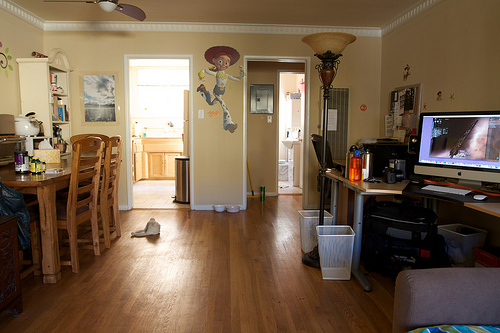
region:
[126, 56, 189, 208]
Daylight is shining from kitchen window.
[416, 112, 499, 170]
A TV is on.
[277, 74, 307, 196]
A light is on in the bathroom.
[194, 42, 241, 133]
A cartoon character is running.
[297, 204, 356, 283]
Two white baskets are on the floor.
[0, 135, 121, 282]
The chairs and table are wood.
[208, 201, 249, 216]
Two bowls are on the floor.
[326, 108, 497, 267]
The computer work station is on a table.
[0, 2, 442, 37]
Crown molding is on the wall.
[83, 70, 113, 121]
The picture is black,white and blue.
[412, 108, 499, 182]
computer monitor on large wooden desk top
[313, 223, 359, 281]
metal screen trash can next to desk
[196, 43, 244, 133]
cartoon character picture on wall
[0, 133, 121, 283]
wooden table and chairs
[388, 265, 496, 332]
side of gray couch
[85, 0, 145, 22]
ceiling fan and light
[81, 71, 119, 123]
image poster on wall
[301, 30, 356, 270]
floor lamp on floor next to desk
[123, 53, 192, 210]
Door way into kitchen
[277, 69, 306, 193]
doorway into bathroom in background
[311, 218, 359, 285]
white mesh trash basket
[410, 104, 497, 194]
large imac computer screen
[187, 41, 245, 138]
image of movie character on wall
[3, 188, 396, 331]
hard wood floors in house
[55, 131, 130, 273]
two wooden chairs with slatted back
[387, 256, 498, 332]
grey arm of stuffed seating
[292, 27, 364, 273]
tall floor lamp with beige shade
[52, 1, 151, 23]
edge of ceiling fan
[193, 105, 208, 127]
light switch on wall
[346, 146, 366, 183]
orange bottle halfway full with blue top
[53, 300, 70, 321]
Part of dark wood grain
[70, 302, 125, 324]
Part of dark wood grain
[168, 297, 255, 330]
Part of dark wood grain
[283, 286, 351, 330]
Part of dark wood grain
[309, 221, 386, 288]
White mesh trash can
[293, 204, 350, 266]
White mesh trash can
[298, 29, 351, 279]
Tall black and grey lamp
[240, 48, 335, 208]
White colored door frame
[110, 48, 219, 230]
White colored door frame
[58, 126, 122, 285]
Several brown colored chairs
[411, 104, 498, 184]
computer monitor on desk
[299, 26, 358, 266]
pole lamp on floor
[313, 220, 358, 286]
white trash can on floor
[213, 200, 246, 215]
pet dishes on floor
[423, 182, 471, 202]
computer keyboard on desk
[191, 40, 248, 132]
character decal on wall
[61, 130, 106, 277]
wooden chair at table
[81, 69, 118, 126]
picture on wall in room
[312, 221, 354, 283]
wire trash can on floor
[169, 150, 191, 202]
metal trash can on floor